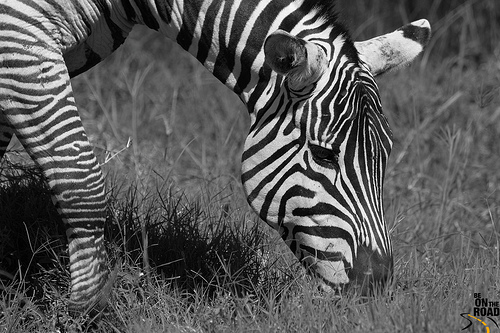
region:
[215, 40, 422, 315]
black and white stripes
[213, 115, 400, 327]
the zebra is eating grass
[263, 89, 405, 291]
A black and grey zebra's head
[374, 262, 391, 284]
A black and grey zebra's nose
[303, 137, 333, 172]
A black and grey zebra's eye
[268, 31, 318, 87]
A black and grey zebra's ear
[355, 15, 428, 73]
A black and grey zebra's ear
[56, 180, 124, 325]
A black and grey zebra's feet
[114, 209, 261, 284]
A black and grey zebra's shadow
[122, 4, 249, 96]
A black and grey zebra's neck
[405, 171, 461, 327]
A black and white grass picture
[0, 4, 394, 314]
A black and grey zebra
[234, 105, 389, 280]
A grey and white zebra's head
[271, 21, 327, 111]
A grey and white zebra's ear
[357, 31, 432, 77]
A grey and white zebra's ear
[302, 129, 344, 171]
A grey and white zebra's eye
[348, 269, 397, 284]
A grey and white zebra's nose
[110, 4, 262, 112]
A grey and white zebra's neck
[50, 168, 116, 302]
A grey and white zebra's feet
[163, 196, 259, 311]
A grey tall grass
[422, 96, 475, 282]
A grey tall grass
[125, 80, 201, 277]
A grey tall grass